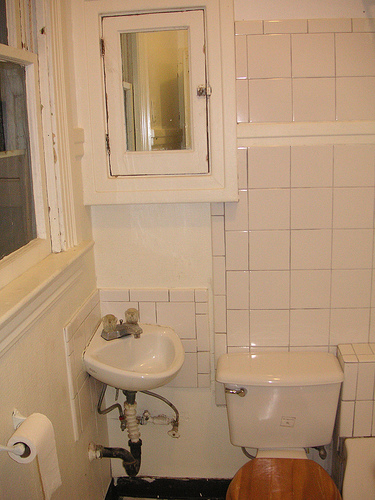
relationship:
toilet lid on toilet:
[226, 457, 342, 499] [215, 351, 343, 498]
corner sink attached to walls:
[82, 309, 183, 393] [64, 288, 212, 442]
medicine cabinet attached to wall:
[71, 1, 239, 209] [72, 1, 373, 479]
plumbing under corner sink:
[87, 381, 179, 478] [82, 309, 183, 393]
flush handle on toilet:
[224, 386, 247, 398] [215, 351, 343, 498]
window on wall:
[0, 1, 52, 289] [0, 0, 111, 499]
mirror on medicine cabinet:
[119, 29, 190, 150] [71, 1, 239, 209]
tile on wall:
[99, 18, 372, 440] [72, 1, 373, 479]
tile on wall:
[63, 288, 105, 441] [0, 0, 111, 499]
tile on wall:
[247, 188, 292, 231] [72, 1, 373, 479]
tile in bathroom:
[247, 188, 292, 231] [0, 1, 373, 498]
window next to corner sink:
[0, 1, 52, 289] [82, 309, 183, 393]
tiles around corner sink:
[64, 287, 211, 441] [82, 309, 183, 393]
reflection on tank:
[249, 353, 304, 421] [215, 353, 343, 450]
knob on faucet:
[124, 310, 140, 324] [102, 308, 144, 342]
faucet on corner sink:
[102, 308, 144, 342] [82, 309, 183, 393]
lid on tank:
[214, 351, 346, 386] [215, 353, 343, 450]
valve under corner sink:
[168, 429, 180, 440] [82, 309, 183, 393]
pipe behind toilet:
[239, 447, 255, 460] [215, 351, 343, 498]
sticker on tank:
[280, 416, 296, 428] [215, 353, 343, 450]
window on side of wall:
[0, 1, 52, 289] [0, 0, 111, 499]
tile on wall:
[247, 146, 292, 191] [72, 1, 373, 479]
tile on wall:
[290, 146, 334, 188] [72, 1, 373, 479]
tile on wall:
[332, 145, 374, 187] [72, 1, 373, 479]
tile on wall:
[290, 188, 332, 230] [72, 1, 373, 479]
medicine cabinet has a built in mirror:
[71, 1, 239, 209] [119, 29, 190, 150]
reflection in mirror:
[119, 29, 192, 153] [119, 29, 190, 150]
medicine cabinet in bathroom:
[71, 1, 239, 209] [0, 1, 373, 498]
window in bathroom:
[0, 1, 52, 289] [0, 1, 373, 498]